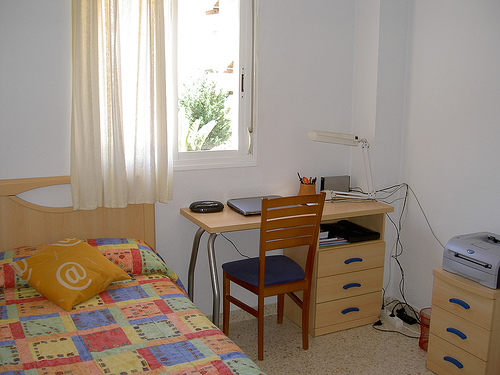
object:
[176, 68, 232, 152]
plant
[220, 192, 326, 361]
chair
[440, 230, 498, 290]
printer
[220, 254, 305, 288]
cushion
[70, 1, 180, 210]
white curtain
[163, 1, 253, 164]
window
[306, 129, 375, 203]
lamp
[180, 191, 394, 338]
desk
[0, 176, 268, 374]
bed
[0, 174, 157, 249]
headboard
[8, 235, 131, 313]
yellow pillow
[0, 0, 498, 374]
bedroom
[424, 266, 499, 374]
stand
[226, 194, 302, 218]
computer